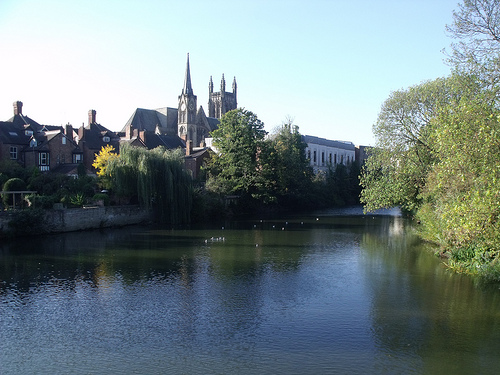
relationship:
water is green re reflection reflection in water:
[0, 202, 499, 372] [8, 217, 492, 374]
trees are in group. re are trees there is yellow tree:
[84, 108, 318, 218] [89, 141, 122, 179]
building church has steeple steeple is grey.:
[173, 52, 210, 151] [176, 50, 239, 124]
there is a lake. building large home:
[0, 202, 499, 372] [0, 100, 48, 185]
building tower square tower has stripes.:
[173, 52, 210, 151] [177, 92, 198, 124]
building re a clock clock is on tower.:
[173, 52, 210, 151] [178, 93, 195, 113]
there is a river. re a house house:
[0, 202, 499, 372] [22, 127, 89, 183]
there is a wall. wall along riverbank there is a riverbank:
[2, 201, 249, 231] [0, 185, 416, 301]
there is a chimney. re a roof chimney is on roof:
[11, 98, 24, 119] [88, 108, 97, 125]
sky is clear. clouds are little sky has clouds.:
[2, 1, 498, 174] [5, 44, 373, 151]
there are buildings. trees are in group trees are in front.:
[3, 53, 404, 214] [3, 106, 366, 212]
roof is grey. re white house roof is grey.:
[301, 133, 356, 147] [301, 133, 358, 152]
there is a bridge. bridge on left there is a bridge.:
[211, 183, 278, 219] [220, 195, 242, 211]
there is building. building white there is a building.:
[302, 133, 357, 185] [302, 133, 358, 176]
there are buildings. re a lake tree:
[3, 53, 404, 214] [99, 141, 197, 218]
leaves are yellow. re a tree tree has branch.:
[89, 141, 122, 179] [93, 146, 116, 176]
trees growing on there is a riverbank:
[399, 95, 499, 285] [0, 205, 149, 232]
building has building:
[112, 46, 352, 183] [173, 52, 210, 151]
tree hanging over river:
[102, 126, 198, 215] [2, 230, 396, 372]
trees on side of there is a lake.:
[352, 5, 483, 285] [0, 204, 499, 374]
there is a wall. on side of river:
[0, 204, 143, 233] [4, 228, 368, 363]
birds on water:
[192, 212, 331, 252] [18, 233, 438, 368]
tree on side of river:
[442, 3, 484, 74] [2, 235, 480, 365]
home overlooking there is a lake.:
[0, 98, 129, 198] [0, 204, 499, 374]